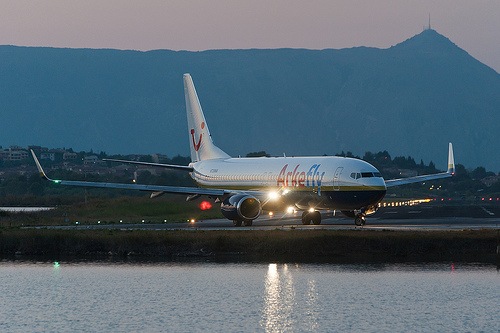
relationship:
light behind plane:
[267, 189, 279, 198] [30, 72, 455, 227]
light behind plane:
[288, 206, 296, 214] [30, 72, 455, 227]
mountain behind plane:
[0, 28, 499, 174] [30, 72, 455, 227]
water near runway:
[0, 249, 499, 331] [1, 199, 500, 229]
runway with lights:
[1, 199, 500, 229] [371, 198, 433, 211]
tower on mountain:
[428, 14, 432, 29] [0, 28, 499, 174]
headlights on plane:
[354, 191, 360, 199] [30, 72, 455, 227]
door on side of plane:
[333, 165, 344, 191] [30, 72, 455, 227]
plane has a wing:
[30, 72, 455, 227] [383, 142, 457, 195]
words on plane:
[276, 163, 326, 200] [30, 72, 455, 227]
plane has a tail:
[30, 72, 455, 227] [181, 74, 231, 163]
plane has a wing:
[30, 72, 455, 227] [29, 148, 226, 200]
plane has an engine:
[30, 72, 455, 227] [221, 195, 262, 221]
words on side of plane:
[276, 163, 326, 200] [30, 72, 455, 227]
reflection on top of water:
[263, 261, 317, 332] [0, 249, 499, 331]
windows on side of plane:
[209, 175, 331, 185] [30, 72, 455, 227]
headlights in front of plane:
[354, 191, 360, 199] [30, 72, 455, 227]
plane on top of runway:
[30, 72, 455, 227] [1, 199, 500, 229]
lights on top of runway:
[371, 198, 433, 211] [1, 199, 500, 229]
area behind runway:
[1, 145, 170, 178] [1, 199, 500, 229]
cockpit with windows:
[348, 158, 386, 192] [350, 170, 382, 181]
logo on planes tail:
[190, 118, 208, 152] [181, 74, 231, 163]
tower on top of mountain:
[428, 14, 432, 29] [0, 28, 499, 174]